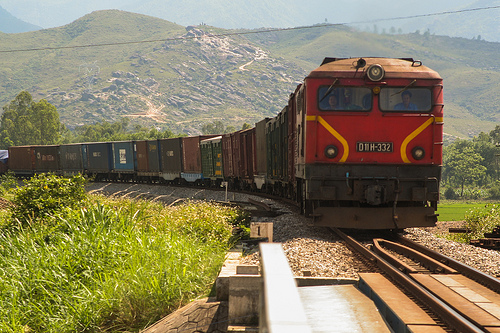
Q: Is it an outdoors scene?
A: Yes, it is outdoors.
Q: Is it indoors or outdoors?
A: It is outdoors.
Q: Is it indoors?
A: No, it is outdoors.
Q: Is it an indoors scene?
A: No, it is outdoors.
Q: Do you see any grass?
A: Yes, there is grass.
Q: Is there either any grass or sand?
A: Yes, there is grass.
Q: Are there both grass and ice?
A: No, there is grass but no ice.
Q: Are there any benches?
A: No, there are no benches.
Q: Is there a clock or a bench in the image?
A: No, there are no benches or clocks.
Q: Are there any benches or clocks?
A: No, there are no benches or clocks.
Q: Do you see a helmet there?
A: No, there are no helmets.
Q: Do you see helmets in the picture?
A: No, there are no helmets.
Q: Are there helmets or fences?
A: No, there are no helmets or fences.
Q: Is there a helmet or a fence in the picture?
A: No, there are no helmets or fences.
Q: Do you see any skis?
A: No, there are no skis.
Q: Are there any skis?
A: No, there are no skis.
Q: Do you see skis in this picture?
A: No, there are no skis.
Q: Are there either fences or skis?
A: No, there are no skis or fences.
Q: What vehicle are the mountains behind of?
A: The mountains are behind the train.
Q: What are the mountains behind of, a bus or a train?
A: The mountains are behind a train.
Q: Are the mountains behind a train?
A: Yes, the mountains are behind a train.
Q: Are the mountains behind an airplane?
A: No, the mountains are behind a train.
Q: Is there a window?
A: Yes, there are windows.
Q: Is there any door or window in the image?
A: Yes, there are windows.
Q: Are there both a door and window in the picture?
A: No, there are windows but no doors.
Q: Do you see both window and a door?
A: No, there are windows but no doors.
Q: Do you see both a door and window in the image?
A: No, there are windows but no doors.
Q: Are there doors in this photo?
A: No, there are no doors.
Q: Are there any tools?
A: No, there are no tools.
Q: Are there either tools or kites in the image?
A: No, there are no tools or kites.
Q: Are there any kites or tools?
A: No, there are no tools or kites.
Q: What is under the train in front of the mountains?
A: The gravel is under the train.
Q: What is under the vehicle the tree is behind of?
A: The gravel is under the train.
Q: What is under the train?
A: The gravel is under the train.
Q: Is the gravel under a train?
A: Yes, the gravel is under a train.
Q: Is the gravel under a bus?
A: No, the gravel is under a train.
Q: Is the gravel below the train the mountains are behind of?
A: Yes, the gravel is below the train.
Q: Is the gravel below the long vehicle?
A: Yes, the gravel is below the train.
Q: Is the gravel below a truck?
A: No, the gravel is below the train.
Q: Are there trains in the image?
A: Yes, there is a train.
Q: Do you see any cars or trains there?
A: Yes, there is a train.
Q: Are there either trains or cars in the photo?
A: Yes, there is a train.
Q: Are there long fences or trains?
A: Yes, there is a long train.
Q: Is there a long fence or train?
A: Yes, there is a long train.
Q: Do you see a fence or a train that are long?
A: Yes, the train is long.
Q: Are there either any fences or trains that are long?
A: Yes, the train is long.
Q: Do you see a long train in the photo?
A: Yes, there is a long train.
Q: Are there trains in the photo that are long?
A: Yes, there is a train that is long.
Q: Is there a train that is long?
A: Yes, there is a train that is long.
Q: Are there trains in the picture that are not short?
A: Yes, there is a long train.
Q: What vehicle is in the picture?
A: The vehicle is a train.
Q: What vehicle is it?
A: The vehicle is a train.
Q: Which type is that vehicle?
A: This is a train.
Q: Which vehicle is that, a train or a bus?
A: This is a train.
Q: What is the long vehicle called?
A: The vehicle is a train.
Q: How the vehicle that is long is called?
A: The vehicle is a train.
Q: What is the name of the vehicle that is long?
A: The vehicle is a train.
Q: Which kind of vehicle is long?
A: The vehicle is a train.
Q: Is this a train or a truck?
A: This is a train.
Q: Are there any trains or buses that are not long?
A: No, there is a train but it is long.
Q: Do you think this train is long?
A: Yes, the train is long.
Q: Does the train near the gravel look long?
A: Yes, the train is long.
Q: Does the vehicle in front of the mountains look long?
A: Yes, the train is long.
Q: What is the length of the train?
A: The train is long.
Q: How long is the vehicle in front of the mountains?
A: The train is long.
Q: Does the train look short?
A: No, the train is long.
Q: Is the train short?
A: No, the train is long.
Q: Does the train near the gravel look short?
A: No, the train is long.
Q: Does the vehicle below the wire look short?
A: No, the train is long.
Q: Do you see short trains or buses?
A: No, there is a train but it is long.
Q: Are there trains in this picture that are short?
A: No, there is a train but it is long.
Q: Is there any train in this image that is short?
A: No, there is a train but it is long.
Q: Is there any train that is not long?
A: No, there is a train but it is long.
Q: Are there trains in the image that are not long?
A: No, there is a train but it is long.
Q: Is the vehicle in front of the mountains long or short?
A: The train is long.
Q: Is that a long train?
A: Yes, that is a long train.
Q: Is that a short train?
A: No, that is a long train.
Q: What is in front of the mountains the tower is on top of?
A: The train is in front of the mountains.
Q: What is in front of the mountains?
A: The train is in front of the mountains.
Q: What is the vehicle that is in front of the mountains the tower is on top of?
A: The vehicle is a train.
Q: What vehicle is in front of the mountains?
A: The vehicle is a train.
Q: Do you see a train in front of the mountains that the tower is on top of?
A: Yes, there is a train in front of the mountains.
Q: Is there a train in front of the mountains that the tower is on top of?
A: Yes, there is a train in front of the mountains.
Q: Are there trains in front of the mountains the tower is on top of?
A: Yes, there is a train in front of the mountains.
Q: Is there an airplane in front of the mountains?
A: No, there is a train in front of the mountains.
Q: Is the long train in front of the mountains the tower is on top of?
A: Yes, the train is in front of the mountains.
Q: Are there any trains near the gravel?
A: Yes, there is a train near the gravel.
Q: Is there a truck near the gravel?
A: No, there is a train near the gravel.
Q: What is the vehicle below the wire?
A: The vehicle is a train.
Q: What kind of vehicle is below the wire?
A: The vehicle is a train.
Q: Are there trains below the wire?
A: Yes, there is a train below the wire.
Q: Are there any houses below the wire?
A: No, there is a train below the wire.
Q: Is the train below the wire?
A: Yes, the train is below the wire.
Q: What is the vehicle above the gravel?
A: The vehicle is a train.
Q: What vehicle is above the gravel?
A: The vehicle is a train.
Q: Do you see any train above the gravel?
A: Yes, there is a train above the gravel.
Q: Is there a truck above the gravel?
A: No, there is a train above the gravel.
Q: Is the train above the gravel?
A: Yes, the train is above the gravel.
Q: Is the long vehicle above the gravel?
A: Yes, the train is above the gravel.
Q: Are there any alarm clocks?
A: No, there are no alarm clocks.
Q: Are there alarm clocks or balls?
A: No, there are no alarm clocks or balls.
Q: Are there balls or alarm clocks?
A: No, there are no alarm clocks or balls.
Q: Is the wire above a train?
A: Yes, the wire is above a train.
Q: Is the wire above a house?
A: No, the wire is above a train.